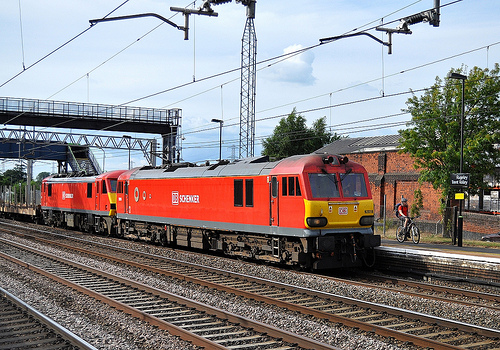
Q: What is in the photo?
A: Train.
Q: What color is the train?
A: Red.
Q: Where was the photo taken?
A: Tracks.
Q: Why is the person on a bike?
A: Transportation.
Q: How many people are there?
A: One.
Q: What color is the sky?
A: Blue.